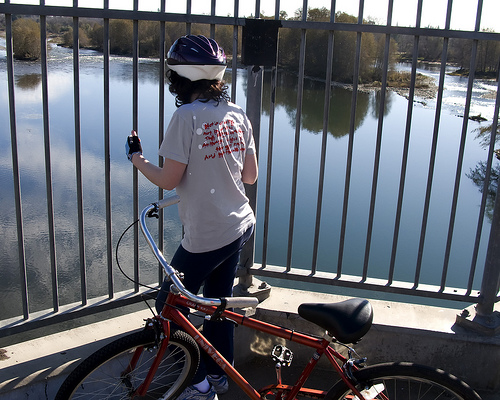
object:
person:
[126, 34, 258, 398]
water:
[0, 39, 499, 345]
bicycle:
[54, 195, 484, 399]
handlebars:
[139, 193, 259, 306]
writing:
[193, 335, 228, 371]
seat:
[297, 298, 374, 343]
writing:
[203, 119, 247, 160]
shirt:
[159, 98, 257, 253]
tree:
[10, 15, 43, 60]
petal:
[270, 341, 293, 368]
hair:
[165, 68, 230, 108]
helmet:
[163, 34, 229, 83]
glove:
[124, 136, 144, 161]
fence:
[2, 0, 500, 340]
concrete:
[2, 282, 499, 398]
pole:
[236, 19, 280, 299]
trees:
[293, 7, 375, 82]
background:
[0, 0, 499, 320]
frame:
[122, 286, 390, 398]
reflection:
[2, 52, 500, 139]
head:
[167, 34, 232, 108]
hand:
[126, 130, 143, 161]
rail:
[133, 1, 140, 293]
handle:
[150, 192, 179, 218]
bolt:
[452, 288, 460, 293]